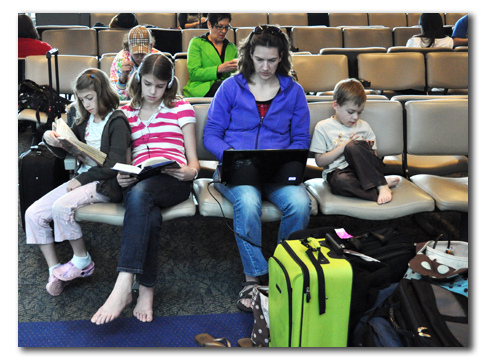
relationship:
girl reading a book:
[23, 68, 130, 299] [51, 119, 108, 166]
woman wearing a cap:
[106, 26, 182, 100] [128, 25, 152, 54]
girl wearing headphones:
[92, 55, 199, 329] [135, 54, 175, 86]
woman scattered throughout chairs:
[109, 23, 165, 101] [26, 12, 474, 225]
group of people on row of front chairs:
[26, 24, 398, 324] [79, 96, 469, 228]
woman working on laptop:
[203, 23, 314, 311] [219, 149, 306, 186]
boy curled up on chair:
[309, 80, 401, 206] [305, 100, 435, 222]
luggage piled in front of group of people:
[248, 229, 472, 345] [26, 24, 398, 324]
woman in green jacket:
[182, 14, 242, 97] [183, 37, 237, 98]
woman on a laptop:
[203, 23, 314, 311] [219, 149, 306, 186]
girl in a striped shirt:
[92, 55, 199, 329] [119, 100, 197, 164]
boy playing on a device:
[309, 80, 401, 206] [350, 138, 372, 144]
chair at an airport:
[305, 100, 435, 222] [17, 14, 471, 349]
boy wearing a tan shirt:
[309, 80, 401, 206] [310, 114, 375, 189]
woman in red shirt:
[17, 14, 49, 57] [19, 38, 52, 57]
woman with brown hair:
[203, 23, 314, 311] [236, 26, 293, 81]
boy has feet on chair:
[309, 80, 401, 206] [305, 100, 435, 222]